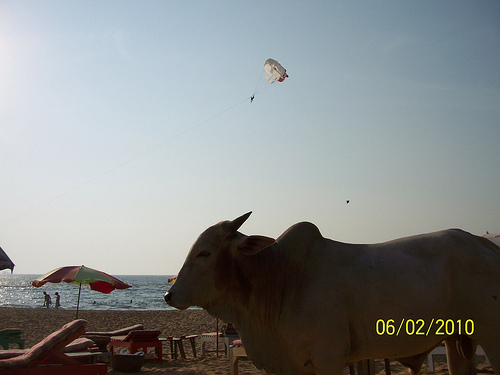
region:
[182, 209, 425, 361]
bull on the beach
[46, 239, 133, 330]
beach umbrella on the sand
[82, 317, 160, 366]
lounge benches on the beach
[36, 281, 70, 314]
couple walking along shore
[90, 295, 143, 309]
people in the water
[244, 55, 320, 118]
parasailing over the water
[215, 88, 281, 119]
person parasailing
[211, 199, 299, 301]
bull has a brown spot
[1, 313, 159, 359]
cushions on the loungers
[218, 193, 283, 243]
horn on the bull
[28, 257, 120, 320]
big umbrella on the beach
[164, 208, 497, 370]
tan cow on the beach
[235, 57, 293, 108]
person flying on kite in the sky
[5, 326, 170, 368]
long wooden beach chairs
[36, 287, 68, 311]
two people walking in the background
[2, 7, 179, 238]
the sky is bright and clear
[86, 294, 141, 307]
two objects in the water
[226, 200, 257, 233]
a horn on the cows head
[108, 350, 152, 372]
basket on the sand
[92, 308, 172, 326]
the sand is brown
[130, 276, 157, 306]
the ocean water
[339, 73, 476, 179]
sky is clear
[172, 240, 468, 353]
an animal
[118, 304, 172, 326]
sand on the beach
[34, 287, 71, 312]
two people standing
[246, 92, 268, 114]
a person in the sky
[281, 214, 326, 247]
a hump on the animal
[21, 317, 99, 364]
beach furniture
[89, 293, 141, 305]
people in the water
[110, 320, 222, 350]
beach furniture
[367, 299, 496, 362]
picture taken 06/02/2010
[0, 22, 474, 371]
scene takes place on beach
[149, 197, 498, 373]
cow is standing on beach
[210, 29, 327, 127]
kite is in the air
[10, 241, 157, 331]
the umbrella is open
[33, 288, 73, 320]
people walking in sand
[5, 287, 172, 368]
the chairs are empty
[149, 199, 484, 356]
the cow is white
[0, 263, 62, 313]
sun shining on water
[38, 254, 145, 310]
the umbrella is multi colored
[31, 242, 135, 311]
umbrella on the beach of different colors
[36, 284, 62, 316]
two people on the beach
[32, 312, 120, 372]
hand reaching out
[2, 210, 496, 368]
hand reaching out to goat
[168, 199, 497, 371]
goat on beach looking at camera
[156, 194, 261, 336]
profile of goat on beach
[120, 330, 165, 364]
outdoor chair on beach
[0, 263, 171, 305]
body of blue water in horizon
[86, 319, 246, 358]
group of outdoor furniter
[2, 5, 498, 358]
blue skies overlooking goat on beach